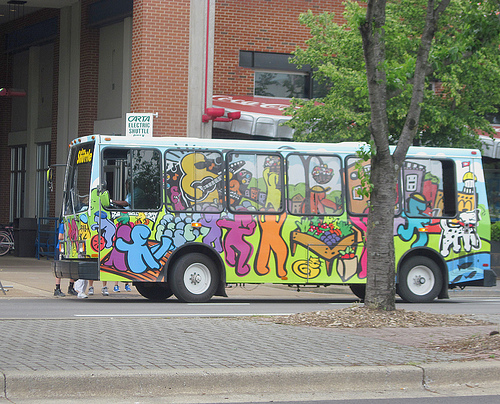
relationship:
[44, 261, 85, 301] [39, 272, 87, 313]
person wearing shoes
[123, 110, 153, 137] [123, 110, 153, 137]
sign has sign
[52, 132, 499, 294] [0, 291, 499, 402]
bus on street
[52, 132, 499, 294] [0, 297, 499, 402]
bus on road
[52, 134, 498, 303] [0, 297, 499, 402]
bus on road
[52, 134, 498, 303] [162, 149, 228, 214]
bus with window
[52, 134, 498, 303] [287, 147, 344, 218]
bus with window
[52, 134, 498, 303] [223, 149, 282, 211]
bus with window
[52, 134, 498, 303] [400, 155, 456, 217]
bus with window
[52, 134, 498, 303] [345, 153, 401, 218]
bus with window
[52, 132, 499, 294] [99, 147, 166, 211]
bus with window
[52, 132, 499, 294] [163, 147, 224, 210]
bus with window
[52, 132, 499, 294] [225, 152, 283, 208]
bus with window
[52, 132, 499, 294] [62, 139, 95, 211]
bus with window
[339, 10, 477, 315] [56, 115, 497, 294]
tree in front of bus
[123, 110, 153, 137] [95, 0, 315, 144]
sign on building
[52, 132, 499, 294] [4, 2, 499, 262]
bus in front of building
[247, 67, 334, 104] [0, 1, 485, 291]
window on building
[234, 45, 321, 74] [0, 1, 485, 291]
window on building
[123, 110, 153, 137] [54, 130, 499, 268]
sign on front of bus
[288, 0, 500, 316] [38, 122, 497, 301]
tree beside bus